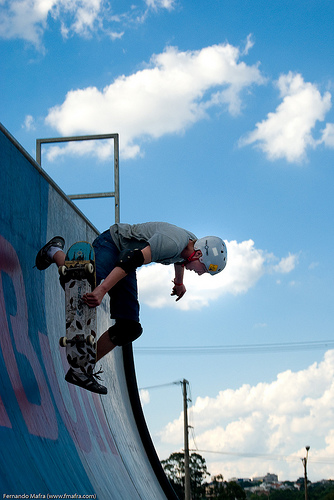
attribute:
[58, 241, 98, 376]
skateboard — blue, white, black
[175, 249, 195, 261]
strap — red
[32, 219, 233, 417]
skateboarder — positioned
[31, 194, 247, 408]
boy — skating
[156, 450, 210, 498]
tree — old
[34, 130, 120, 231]
handbar — light gray, metal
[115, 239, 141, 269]
elbow pad — black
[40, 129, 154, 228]
pole — telephone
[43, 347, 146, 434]
ramp — blue, white, wooden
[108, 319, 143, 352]
pad — black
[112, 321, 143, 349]
kneepad — black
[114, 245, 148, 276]
pad — black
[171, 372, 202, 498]
pole — light gray, metal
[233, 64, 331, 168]
cloud — puffy, white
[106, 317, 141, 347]
knee pad — black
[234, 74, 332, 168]
cloud — white, fluffy, thick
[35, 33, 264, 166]
cloud — white, fluffy, thick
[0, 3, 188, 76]
cloud — white, fluffy, thick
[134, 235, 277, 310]
cloud — white, fluffy, thick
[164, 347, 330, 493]
cloud — white, fluffy, thick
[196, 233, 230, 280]
helmet — white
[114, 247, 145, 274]
elbow pad — black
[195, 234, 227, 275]
helmet — white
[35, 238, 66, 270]
shoes — black, white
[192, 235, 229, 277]
helmet — gray, white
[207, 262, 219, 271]
sticker — yellow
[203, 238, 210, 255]
sticker — blue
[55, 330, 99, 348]
wheels — white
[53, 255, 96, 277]
wheels — white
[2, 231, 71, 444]
letter — red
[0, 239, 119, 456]
lettering — red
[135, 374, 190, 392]
wires — electric